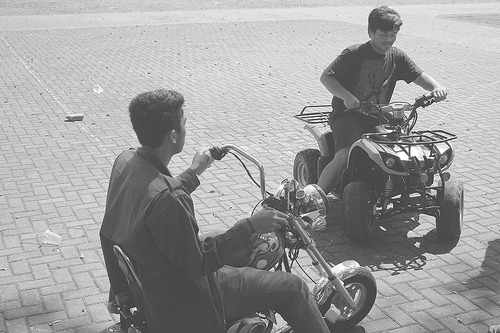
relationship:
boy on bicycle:
[106, 84, 331, 328] [106, 145, 378, 326]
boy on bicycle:
[314, 4, 450, 191] [98, 142, 378, 333]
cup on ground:
[32, 222, 64, 247] [26, 155, 71, 192]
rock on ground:
[66, 113, 84, 119] [12, 49, 120, 144]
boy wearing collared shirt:
[97, 88, 330, 333] [100, 145, 253, 275]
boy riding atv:
[316, 5, 448, 196] [292, 92, 464, 243]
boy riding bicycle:
[97, 88, 330, 333] [98, 142, 378, 333]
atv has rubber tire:
[292, 92, 464, 243] [342, 181, 375, 243]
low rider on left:
[99, 88, 330, 333] [3, 0, 249, 330]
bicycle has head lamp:
[98, 142, 378, 333] [299, 183, 329, 220]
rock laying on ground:
[65, 113, 84, 121] [1, 0, 498, 332]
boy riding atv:
[316, 5, 448, 196] [285, 87, 475, 246]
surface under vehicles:
[2, 22, 498, 331] [106, 144, 381, 331]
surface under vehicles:
[2, 22, 498, 331] [291, 87, 468, 239]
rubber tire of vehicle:
[312, 259, 378, 332] [278, 117, 497, 249]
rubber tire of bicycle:
[312, 259, 378, 332] [98, 142, 378, 333]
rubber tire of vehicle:
[436, 173, 463, 245] [293, 102, 465, 240]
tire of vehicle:
[319, 260, 376, 329] [98, 142, 377, 331]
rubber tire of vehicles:
[335, 179, 372, 249] [200, 128, 373, 316]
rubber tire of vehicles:
[436, 173, 463, 245] [200, 128, 373, 316]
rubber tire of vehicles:
[291, 145, 319, 190] [200, 128, 373, 316]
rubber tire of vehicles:
[299, 262, 384, 332] [200, 128, 373, 316]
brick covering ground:
[100, 28, 257, 69] [8, 14, 476, 182]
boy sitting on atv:
[97, 88, 330, 333] [281, 81, 486, 247]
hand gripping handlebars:
[195, 126, 314, 259] [333, 90, 450, 131]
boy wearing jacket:
[97, 88, 330, 333] [75, 86, 324, 330]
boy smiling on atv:
[316, 5, 448, 196] [293, 72, 488, 282]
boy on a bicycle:
[316, 5, 448, 196] [98, 142, 378, 333]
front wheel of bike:
[304, 253, 378, 330] [63, 142, 378, 330]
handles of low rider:
[216, 127, 324, 219] [89, 140, 377, 330]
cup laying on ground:
[32, 221, 74, 261] [5, 10, 115, 330]